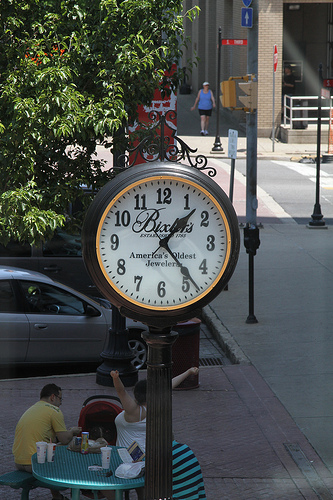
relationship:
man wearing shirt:
[13, 383, 82, 473] [9, 401, 63, 459]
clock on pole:
[82, 164, 240, 318] [142, 323, 178, 498]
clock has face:
[82, 164, 240, 318] [98, 176, 226, 306]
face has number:
[98, 176, 226, 306] [156, 181, 171, 207]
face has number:
[98, 176, 226, 306] [204, 232, 219, 256]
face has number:
[98, 176, 226, 306] [175, 273, 192, 297]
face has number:
[98, 176, 226, 306] [134, 274, 147, 293]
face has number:
[98, 176, 226, 306] [102, 232, 120, 251]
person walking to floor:
[190, 82, 216, 136] [0, 94, 333, 496]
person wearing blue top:
[191, 80, 216, 138] [196, 88, 213, 111]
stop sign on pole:
[269, 44, 281, 73] [267, 84, 278, 139]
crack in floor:
[248, 472, 287, 481] [0, 94, 333, 496]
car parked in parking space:
[1, 260, 170, 373] [2, 323, 235, 381]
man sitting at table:
[13, 383, 82, 473] [25, 439, 152, 498]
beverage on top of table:
[101, 444, 111, 469] [29, 438, 143, 489]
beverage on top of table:
[47, 442, 57, 465] [29, 438, 143, 489]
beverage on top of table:
[36, 439, 46, 461] [29, 438, 143, 489]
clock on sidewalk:
[82, 164, 240, 318] [176, 94, 332, 156]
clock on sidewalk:
[82, 164, 240, 318] [203, 224, 331, 498]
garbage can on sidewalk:
[165, 317, 200, 393] [1, 361, 332, 498]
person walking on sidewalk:
[190, 82, 216, 136] [198, 127, 279, 176]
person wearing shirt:
[169, 431, 205, 499] [171, 443, 205, 499]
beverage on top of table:
[36, 441, 47, 463] [43, 421, 184, 479]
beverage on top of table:
[47, 443, 55, 462] [43, 421, 184, 479]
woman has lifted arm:
[108, 367, 199, 453] [111, 378, 136, 415]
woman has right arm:
[108, 367, 199, 453] [171, 366, 200, 388]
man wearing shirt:
[11, 380, 78, 473] [12, 401, 71, 464]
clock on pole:
[116, 162, 226, 337] [138, 327, 180, 498]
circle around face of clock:
[92, 169, 232, 309] [80, 143, 239, 329]